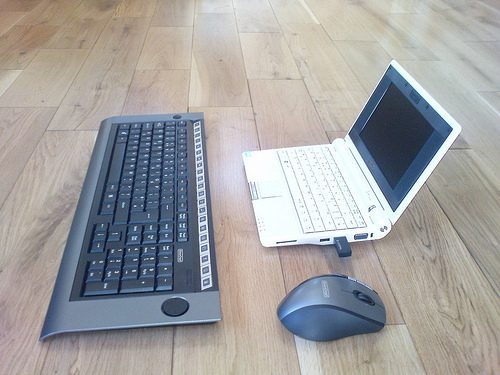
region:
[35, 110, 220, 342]
a black and grey keyboard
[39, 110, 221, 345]
a wireless computer keyboard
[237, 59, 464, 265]
a white netbook computer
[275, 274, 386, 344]
a black and grey mouse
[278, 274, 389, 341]
a wireless computer mouse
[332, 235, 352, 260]
a black USB dongle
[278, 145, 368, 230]
a white computer keybaord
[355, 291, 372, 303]
a mouse scroll wheel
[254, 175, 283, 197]
a computer track pad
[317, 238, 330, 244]
a computer USB port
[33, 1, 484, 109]
The floor is made of wood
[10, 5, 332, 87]
The color of the floor is brown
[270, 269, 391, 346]
The mouse is on the floor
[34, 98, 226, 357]
The wireless keyboard is on the floor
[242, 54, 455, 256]
The laptop is on the floor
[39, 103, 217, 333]
The keyboard is gray and black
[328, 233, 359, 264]
The USB stick in the laptop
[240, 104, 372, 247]
The laptop is the color white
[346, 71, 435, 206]
The screen to the laptop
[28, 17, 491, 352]
The laptop, keyboard, and mouse are all on the floor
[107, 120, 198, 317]
A keyboard on the floor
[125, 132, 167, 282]
The keypad of the board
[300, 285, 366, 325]
The mouse on the floor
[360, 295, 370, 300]
The wheel of the mouse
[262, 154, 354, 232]
A laptop on the floor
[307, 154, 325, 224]
The keypad of the laptop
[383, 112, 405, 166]
The laptop screen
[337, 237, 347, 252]
A black flash stick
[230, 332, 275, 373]
The wooden floor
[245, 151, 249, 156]
A green mark on the lap top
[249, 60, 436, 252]
white laptop on floor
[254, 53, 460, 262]
laptop is opened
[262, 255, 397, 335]
black mouse on the floor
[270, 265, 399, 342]
wireless mouse on the floor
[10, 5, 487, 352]
floor made of wood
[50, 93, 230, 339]
black keyboard on the floor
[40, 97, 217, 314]
wireless keyboard on the floor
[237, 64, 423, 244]
laptop is turned off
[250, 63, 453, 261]
USB on the side of laptop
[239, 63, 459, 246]
laptop is small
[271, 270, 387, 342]
a computer mouse on a wooden floor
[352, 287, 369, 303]
a scrolling wheel on the top of the mouse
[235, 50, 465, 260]
a white laptop on the wooden floor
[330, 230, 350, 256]
a USB drive plugged into the laptop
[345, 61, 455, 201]
a black screen on the laptop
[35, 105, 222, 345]
a black keyboard on the wooden floor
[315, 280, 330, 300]
a logo on the back of the mouse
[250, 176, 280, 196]
a track pad on the top of the laptop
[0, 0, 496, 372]
a wooden hardwood floor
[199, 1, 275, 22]
a reflection of light on the wooden floor